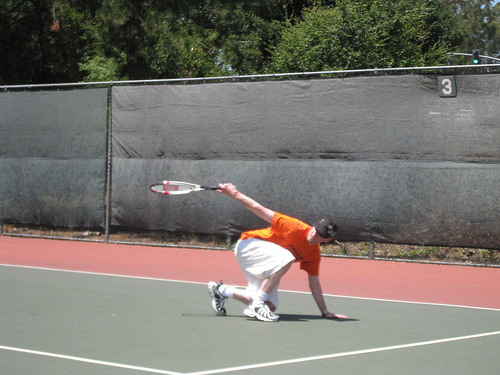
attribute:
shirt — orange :
[239, 211, 321, 276]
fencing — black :
[1, 69, 493, 249]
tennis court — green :
[20, 57, 498, 339]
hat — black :
[299, 202, 369, 247]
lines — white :
[17, 310, 471, 368]